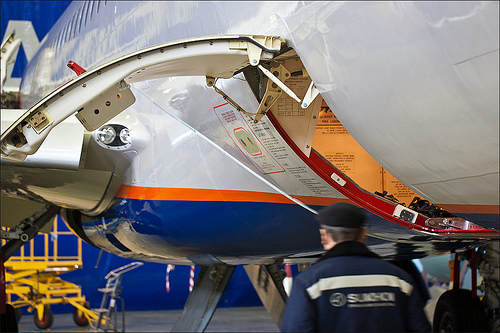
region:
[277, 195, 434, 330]
Airline employee servicing a plane.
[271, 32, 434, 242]
Open airplane cargo hatch.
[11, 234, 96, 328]
Yellow device for servicing an airplane.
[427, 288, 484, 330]
Airplane wheel and tire.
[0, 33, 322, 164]
Door of the cargo area of an airplane.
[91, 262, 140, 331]
Metal stool.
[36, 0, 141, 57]
Windows of a white commercial airliner.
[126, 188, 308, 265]
Blue and orange underbelly of an airplane.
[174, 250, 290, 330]
Apparatus that helps to service the plane.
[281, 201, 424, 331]
Airline employee wearing a hat.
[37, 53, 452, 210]
large open airplane door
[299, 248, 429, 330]
blue and white jacket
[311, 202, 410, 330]
man wearing a blue and white jacket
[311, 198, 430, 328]
man wearing a blue jacket with white words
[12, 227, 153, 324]
yellow metal lift with wheels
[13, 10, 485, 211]
large airplane with open door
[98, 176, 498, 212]
orange stripe on side of airplane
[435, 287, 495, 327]
wheel of an airplane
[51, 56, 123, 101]
red handle on a airplane door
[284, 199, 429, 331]
a man in blue jacket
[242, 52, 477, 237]
open hatch of a plane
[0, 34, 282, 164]
a door on a plane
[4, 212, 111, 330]
a yellow metal cart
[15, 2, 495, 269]
the underside of a plane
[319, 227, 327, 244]
ear of a man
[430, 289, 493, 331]
wheel of a plane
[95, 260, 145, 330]
a metal stair set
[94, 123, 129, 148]
lights on a plane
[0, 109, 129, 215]
wing of a plane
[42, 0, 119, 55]
windows on side of anairplane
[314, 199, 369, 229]
man is wearing a black hat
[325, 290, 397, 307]
logo on a blue jacket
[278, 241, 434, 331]
blue jacket being worn by man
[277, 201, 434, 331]
man standing next to a airplane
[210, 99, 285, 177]
sign painted on a side of an airplane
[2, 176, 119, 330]
yellow lift used for airplanes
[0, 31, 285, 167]
airplane door that is ajar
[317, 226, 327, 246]
blurry ear of a man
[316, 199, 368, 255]
the back of a mans head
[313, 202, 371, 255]
head of a person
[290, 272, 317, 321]
arm of a person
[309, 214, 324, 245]
ear of a person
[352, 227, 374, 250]
ear of a person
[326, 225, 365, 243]
hair of a person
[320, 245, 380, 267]
neck of a person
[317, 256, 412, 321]
back of a person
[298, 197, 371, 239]
hat of a person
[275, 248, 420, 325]
jacket of a person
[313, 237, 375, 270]
collar of a person